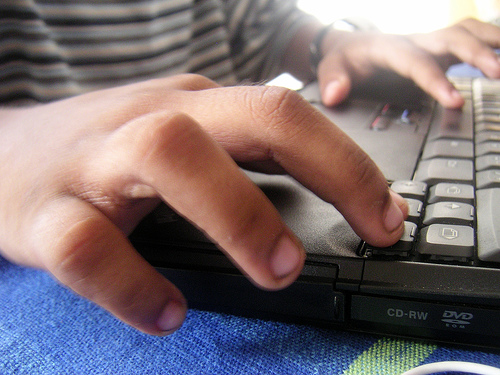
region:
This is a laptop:
[389, 65, 497, 237]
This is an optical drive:
[353, 289, 498, 344]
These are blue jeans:
[53, 320, 158, 361]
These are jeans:
[43, 307, 100, 369]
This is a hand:
[75, 126, 155, 196]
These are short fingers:
[161, 157, 262, 267]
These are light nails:
[245, 218, 330, 284]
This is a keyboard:
[405, 125, 495, 253]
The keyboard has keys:
[405, 205, 481, 270]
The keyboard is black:
[380, 111, 497, 182]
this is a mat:
[14, 295, 75, 345]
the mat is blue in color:
[61, 333, 98, 363]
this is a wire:
[388, 357, 493, 374]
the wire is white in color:
[398, 353, 498, 373]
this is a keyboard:
[220, 61, 492, 356]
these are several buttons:
[428, 144, 490, 273]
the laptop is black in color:
[283, 193, 310, 215]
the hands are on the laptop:
[46, 1, 481, 323]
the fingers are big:
[68, 78, 435, 365]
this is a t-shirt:
[83, 0, 196, 53]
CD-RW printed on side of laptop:
[385, 304, 430, 326]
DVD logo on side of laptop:
[438, 305, 473, 332]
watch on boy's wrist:
[300, 13, 364, 84]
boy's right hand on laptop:
[2, 63, 412, 341]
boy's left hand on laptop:
[285, 11, 499, 110]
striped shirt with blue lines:
[2, 0, 315, 125]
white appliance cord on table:
[395, 358, 498, 373]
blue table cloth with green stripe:
[1, 257, 498, 373]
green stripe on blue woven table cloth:
[335, 337, 438, 372]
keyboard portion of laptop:
[371, 70, 496, 269]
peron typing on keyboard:
[1, 5, 497, 341]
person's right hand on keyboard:
[4, 69, 414, 339]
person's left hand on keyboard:
[313, 13, 498, 98]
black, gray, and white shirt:
[1, 6, 296, 111]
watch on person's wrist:
[303, 26, 332, 71]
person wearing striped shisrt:
[2, 4, 498, 339]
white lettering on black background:
[379, 294, 483, 338]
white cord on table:
[402, 348, 483, 374]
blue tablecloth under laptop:
[3, 263, 481, 374]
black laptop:
[112, 19, 497, 339]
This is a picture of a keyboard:
[313, 27, 484, 228]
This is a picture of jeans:
[6, 270, 97, 352]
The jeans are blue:
[67, 313, 121, 373]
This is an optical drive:
[392, 215, 492, 372]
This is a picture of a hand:
[69, 95, 281, 233]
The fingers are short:
[101, 127, 316, 261]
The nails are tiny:
[264, 196, 347, 293]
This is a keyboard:
[377, 156, 472, 254]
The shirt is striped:
[77, 26, 172, 78]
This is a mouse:
[327, 102, 353, 121]